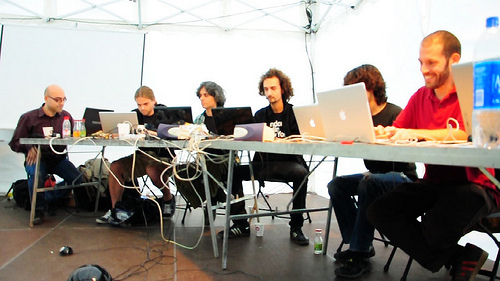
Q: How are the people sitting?
A: Around a table.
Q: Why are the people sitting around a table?
A: They are using computers.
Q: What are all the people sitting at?
A: Tables.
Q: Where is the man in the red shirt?
A: Right.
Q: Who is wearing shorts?
A: Man second from the left.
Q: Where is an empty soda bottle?
A: Right corner of the table.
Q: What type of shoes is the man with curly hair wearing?
A: Adidas.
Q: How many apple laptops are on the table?
A: Three.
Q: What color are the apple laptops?
A: Silver.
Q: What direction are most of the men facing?
A: Left.